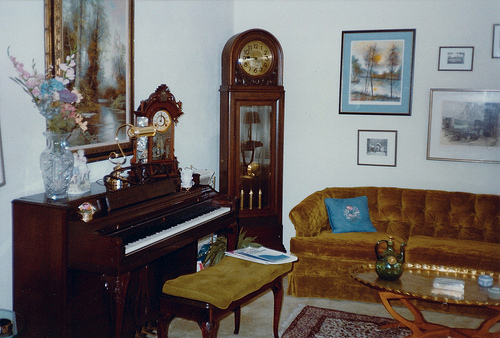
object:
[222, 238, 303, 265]
stack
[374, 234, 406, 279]
figurine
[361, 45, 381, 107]
trees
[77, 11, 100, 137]
trees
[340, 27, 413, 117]
frame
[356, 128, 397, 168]
frame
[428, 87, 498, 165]
frame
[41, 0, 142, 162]
frame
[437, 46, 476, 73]
frame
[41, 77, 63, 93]
flowers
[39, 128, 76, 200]
pot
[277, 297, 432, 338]
rug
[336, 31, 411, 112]
painting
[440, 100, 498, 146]
picture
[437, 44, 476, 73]
picture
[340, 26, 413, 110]
picture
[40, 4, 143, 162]
picture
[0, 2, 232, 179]
wall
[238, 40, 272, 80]
clock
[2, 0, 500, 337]
room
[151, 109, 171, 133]
clock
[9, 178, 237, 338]
piano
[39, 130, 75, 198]
vase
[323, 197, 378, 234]
pillow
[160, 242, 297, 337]
bench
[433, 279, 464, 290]
paper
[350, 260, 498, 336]
coffee table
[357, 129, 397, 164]
picture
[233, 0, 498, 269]
wall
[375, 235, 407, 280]
teapot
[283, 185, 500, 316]
couch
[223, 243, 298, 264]
paper